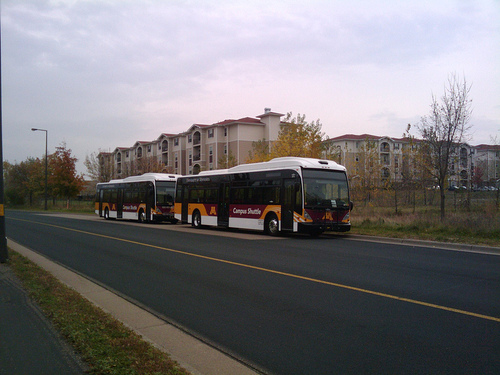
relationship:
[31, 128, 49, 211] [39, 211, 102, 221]
street lamp on sidewalk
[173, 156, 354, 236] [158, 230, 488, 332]
bus parked on road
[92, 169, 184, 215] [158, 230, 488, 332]
bus parked on road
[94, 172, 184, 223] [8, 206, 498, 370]
bus parked on road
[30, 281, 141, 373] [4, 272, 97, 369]
grass on ground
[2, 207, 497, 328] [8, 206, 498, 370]
yellow paint on road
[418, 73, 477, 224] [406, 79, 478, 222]
bare tree on tree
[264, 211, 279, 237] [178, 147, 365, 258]
wheel on bus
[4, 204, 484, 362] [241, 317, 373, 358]
blacktop on road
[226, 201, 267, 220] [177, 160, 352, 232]
writing on bus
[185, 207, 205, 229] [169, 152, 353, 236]
wheel on bus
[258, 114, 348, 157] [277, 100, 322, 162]
leaves are on tree